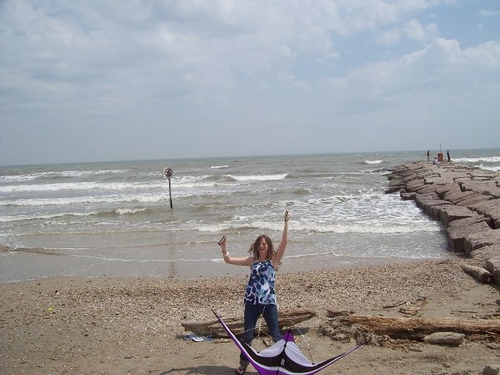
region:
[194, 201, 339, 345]
this is a woman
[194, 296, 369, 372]
this is a kite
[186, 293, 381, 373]
the kite is upside down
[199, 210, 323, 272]
woman with arms up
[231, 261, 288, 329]
woman wearing blue print shirt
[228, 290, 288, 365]
woman wearing blue pants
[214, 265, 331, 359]
white string on kite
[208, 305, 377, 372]
kite is purple and black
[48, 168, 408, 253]
ocean water is brown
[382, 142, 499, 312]
rock jetty next to the woman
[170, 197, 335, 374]
woman holding a kite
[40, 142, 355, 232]
the water is murky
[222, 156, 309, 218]
the water is murky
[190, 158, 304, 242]
the water is murky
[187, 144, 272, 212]
the water is murky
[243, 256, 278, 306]
A blue pattern on a shirt.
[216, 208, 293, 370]
A woman standing on the beach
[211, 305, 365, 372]
A purple kite on the ground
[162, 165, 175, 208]
A sign in the water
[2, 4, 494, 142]
A sky of gray clouds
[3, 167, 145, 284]
Water on the shore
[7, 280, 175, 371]
Light brown sand at the beach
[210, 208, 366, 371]
A woman holding handles of a purple kite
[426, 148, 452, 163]
A couple of people standing on the rocks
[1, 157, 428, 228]
Gray water of the ocean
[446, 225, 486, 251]
large grey colored stone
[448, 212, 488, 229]
large grey colored stone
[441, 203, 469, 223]
large grey colored stone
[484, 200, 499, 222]
large grey colored stone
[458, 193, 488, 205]
large grey colored stone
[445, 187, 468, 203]
large grey colored stone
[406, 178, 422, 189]
large grey colored stone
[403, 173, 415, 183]
large grey colored stone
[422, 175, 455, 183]
large grey colored stone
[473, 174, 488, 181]
large grey colored stone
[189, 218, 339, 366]
this is a lady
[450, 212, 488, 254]
this is a rock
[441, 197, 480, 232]
this is a rock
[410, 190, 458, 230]
this is a rock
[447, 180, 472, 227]
this is a rock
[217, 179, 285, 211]
this is a wave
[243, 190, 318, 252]
this is a wave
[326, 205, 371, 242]
this is a wave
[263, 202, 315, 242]
this is a wave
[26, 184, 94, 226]
this is a wave